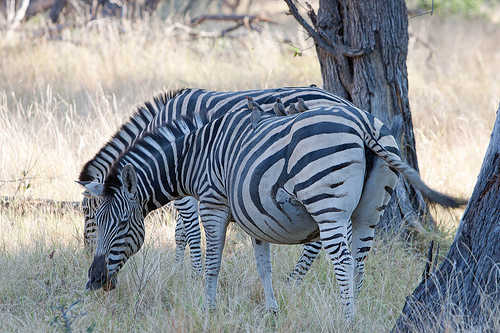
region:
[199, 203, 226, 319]
the leg of a zebra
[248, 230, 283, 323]
the leg of a zebra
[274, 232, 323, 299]
the leg of a zebra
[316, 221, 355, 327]
the leg of a zebra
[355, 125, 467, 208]
the tail of a zebra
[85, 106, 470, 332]
a zebra eating grass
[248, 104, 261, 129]
a bird resting on a zebra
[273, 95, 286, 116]
a bird resting on a zebra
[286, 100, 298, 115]
a bird resting on a zebra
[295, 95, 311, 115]
a bird resting on a zebra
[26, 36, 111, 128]
brown grass covering the ground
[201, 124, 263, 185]
stripes on the side of the zebra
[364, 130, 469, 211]
tail swishing on the zebra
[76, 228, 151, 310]
zebra eating the grass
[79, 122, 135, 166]
short striped mane on the zebra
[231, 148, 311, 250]
zebra appears to be pregnant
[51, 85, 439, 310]
zebras grazing in the shade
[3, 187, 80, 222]
tree laying in the grass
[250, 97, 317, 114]
birds on the zebras back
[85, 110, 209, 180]
The mane of the zebras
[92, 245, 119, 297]
The zebras open mouth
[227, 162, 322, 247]
The pregnant belly of the zebra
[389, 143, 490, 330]
The trunk of the tree in front of the zebra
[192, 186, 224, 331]
The zebras front leg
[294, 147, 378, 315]
The zebras back legs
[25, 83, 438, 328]
Two zebras standing one of them is pregnant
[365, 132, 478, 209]
the tail of a zebra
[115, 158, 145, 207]
the ear of a zebra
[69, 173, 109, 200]
the ear of a zebra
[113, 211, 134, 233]
the eye of a zebra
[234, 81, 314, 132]
birds on the back of a zebra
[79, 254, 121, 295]
the nose of a zebra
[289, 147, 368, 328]
the hind leg of a zebra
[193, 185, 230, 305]
the front leg of a zebra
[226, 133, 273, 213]
the stripes on a zebra's coat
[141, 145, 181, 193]
the stripes on a zebra's coat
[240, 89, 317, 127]
birds perched on zebra's back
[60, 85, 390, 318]
zebras grazing on yellow grass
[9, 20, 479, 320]
field of yellow grass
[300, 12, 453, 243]
rough bark of tree trunk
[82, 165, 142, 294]
zebra has mouth open eating grass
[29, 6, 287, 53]
fallen branches in the grass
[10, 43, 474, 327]
the grass is tall and dry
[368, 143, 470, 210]
zebra's tail is swinging to the right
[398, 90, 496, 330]
edge of a gray tree trunk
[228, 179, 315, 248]
belly of a zebra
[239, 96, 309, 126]
Birds on a zebra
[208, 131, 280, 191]
Stripes on a zebra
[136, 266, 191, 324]
Grass in a field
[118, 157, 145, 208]
Ear on a zebra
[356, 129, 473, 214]
Tail on a zebra